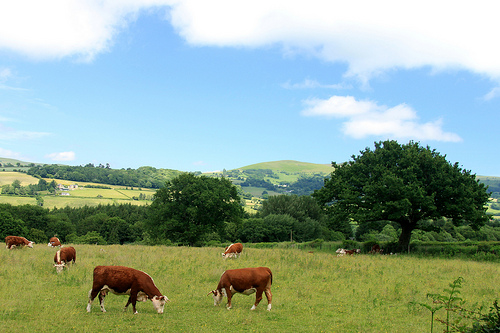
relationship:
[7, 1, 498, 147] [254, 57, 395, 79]
clouds in sky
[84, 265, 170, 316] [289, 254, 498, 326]
cow grazing in field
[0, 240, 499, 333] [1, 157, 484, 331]
grass growing on ground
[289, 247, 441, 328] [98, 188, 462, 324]
grass on field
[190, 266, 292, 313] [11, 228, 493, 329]
cow on field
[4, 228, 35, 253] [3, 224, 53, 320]
brown cow in in field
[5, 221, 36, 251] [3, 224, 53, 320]
cow grazing in in field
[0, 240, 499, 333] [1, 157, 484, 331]
grass on ground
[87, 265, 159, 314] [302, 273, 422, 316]
cow grazing in field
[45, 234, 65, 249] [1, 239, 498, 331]
cow grazing in field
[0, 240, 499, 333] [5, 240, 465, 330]
grass on ground